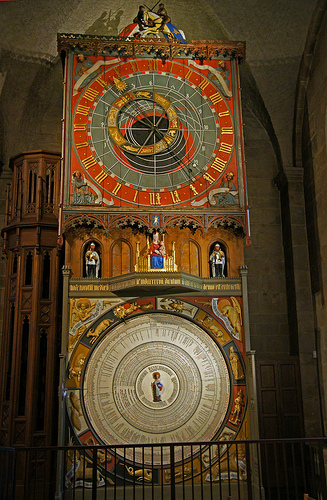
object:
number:
[133, 190, 139, 202]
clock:
[63, 49, 245, 215]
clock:
[65, 46, 240, 210]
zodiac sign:
[82, 314, 113, 344]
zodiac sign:
[158, 293, 196, 315]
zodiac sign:
[225, 343, 246, 381]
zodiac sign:
[64, 389, 87, 434]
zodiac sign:
[112, 297, 149, 318]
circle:
[56, 31, 252, 244]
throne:
[135, 232, 180, 273]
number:
[82, 155, 97, 169]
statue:
[210, 244, 225, 278]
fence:
[0, 438, 325, 500]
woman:
[145, 230, 172, 283]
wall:
[168, 113, 179, 120]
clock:
[63, 286, 248, 489]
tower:
[55, 0, 266, 495]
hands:
[110, 78, 209, 173]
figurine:
[85, 242, 100, 278]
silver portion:
[82, 310, 231, 467]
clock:
[53, 34, 262, 499]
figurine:
[149, 232, 166, 268]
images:
[68, 296, 120, 354]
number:
[76, 142, 88, 149]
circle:
[135, 363, 180, 410]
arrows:
[99, 76, 216, 187]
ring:
[108, 91, 179, 156]